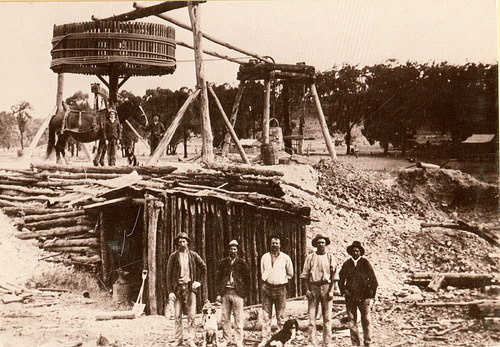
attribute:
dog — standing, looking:
[154, 288, 307, 346]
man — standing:
[287, 228, 346, 336]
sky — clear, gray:
[327, 16, 435, 56]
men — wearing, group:
[187, 196, 387, 309]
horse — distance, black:
[39, 84, 167, 167]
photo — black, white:
[89, 28, 434, 344]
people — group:
[83, 227, 381, 342]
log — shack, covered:
[141, 15, 221, 166]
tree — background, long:
[331, 43, 471, 163]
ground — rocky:
[365, 166, 431, 219]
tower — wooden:
[246, 57, 306, 148]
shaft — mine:
[77, 144, 371, 346]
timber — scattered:
[10, 166, 114, 242]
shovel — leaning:
[128, 279, 150, 313]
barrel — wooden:
[255, 136, 297, 173]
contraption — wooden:
[174, 162, 301, 229]